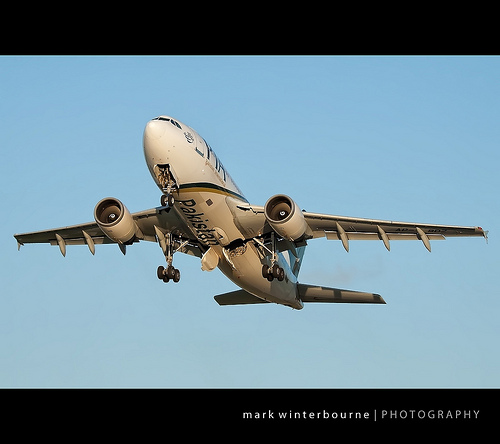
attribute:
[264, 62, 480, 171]
sky — blue